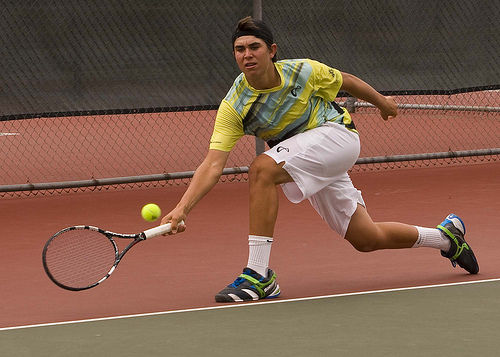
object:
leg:
[307, 167, 437, 253]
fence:
[0, 0, 499, 201]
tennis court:
[2, 0, 499, 357]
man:
[160, 20, 478, 303]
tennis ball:
[141, 203, 161, 222]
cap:
[231, 19, 275, 63]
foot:
[213, 267, 281, 303]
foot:
[440, 213, 479, 274]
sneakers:
[214, 267, 281, 303]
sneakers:
[434, 212, 480, 275]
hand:
[159, 206, 187, 237]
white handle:
[142, 219, 185, 240]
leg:
[248, 125, 340, 266]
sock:
[246, 235, 273, 278]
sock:
[410, 225, 451, 251]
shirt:
[208, 59, 358, 152]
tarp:
[0, 0, 500, 123]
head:
[231, 19, 277, 80]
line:
[0, 278, 499, 331]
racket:
[40, 225, 187, 291]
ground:
[338, 263, 428, 283]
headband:
[231, 26, 272, 44]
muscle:
[264, 182, 280, 227]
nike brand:
[267, 239, 274, 243]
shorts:
[261, 121, 366, 240]